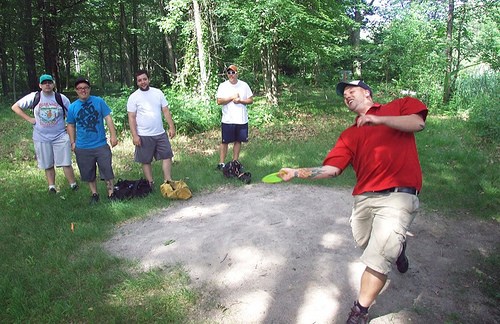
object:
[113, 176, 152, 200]
backpack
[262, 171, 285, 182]
disc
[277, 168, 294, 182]
hand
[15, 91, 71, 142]
shirt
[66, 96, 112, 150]
shirt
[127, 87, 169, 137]
shirt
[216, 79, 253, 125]
shirt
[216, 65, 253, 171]
man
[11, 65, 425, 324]
people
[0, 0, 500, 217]
background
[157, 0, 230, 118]
tree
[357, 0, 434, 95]
tree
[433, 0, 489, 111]
tree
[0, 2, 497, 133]
green leaves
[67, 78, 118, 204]
he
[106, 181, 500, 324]
ground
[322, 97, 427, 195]
polo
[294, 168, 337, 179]
arm tattoos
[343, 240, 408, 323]
shoes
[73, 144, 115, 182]
shorts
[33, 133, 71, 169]
shorts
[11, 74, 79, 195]
man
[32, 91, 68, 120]
backpack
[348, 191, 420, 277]
shorts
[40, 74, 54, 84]
blue cap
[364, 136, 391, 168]
red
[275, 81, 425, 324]
he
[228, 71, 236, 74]
sunglasses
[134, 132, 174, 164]
grey shorts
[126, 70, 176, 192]
man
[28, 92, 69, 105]
shoulder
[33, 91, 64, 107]
straps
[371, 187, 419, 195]
belt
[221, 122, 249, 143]
shorts